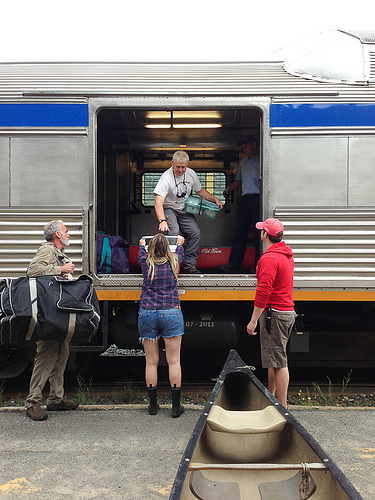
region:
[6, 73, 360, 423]
A scene at a train station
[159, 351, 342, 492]
Front part of a canoie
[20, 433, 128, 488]
Grey patch of train platform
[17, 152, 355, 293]
A train's cargo hold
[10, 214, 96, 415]
Man carrying a large black bag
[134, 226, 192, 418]
Woman wearing jens shorts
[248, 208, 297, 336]
Man wearing red sweatshirt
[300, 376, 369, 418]
Edge of the train platform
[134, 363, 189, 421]
Person wearing black boots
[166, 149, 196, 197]
Man with grey hair and white shirt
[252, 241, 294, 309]
a red coat with a hood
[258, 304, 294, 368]
a pair of olive colored shorts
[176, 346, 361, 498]
a small row boat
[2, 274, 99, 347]
large black dufflebag with white trim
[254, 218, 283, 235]
a red ball cap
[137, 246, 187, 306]
purple long sleeve plaid shirt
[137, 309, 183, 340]
a pair of cut off shorts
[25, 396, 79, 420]
a pair of dingy brown shoes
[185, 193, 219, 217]
blue plastic container with lid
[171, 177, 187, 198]
a pair of sunglasses with neck strap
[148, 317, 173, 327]
LADY WEARING BLUE SHORTS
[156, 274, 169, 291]
LADY HAS ON PLAID SHIRT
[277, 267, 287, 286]
MAN HAS ON A RED SWEATER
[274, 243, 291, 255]
HOOD ON THE BACK OF SWEATER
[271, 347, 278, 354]
MAN HAS ON SHORTS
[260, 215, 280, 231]
MAN WEARING A RED CAP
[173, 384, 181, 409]
LADY HAS ON BROWN BOOTS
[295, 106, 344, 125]
BLUE ON THE TRAIN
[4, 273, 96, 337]
BIG BAG ON MAN SHOULDER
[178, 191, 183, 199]
GLASSES ON A STRING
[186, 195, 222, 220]
man holding a green suitcase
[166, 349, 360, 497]
a small boat on a cement road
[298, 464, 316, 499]
rope attached to a wooden stick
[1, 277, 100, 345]
a big black bag with white lines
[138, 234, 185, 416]
a woman reaching to grab her luggage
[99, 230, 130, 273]
a purple bag inside a train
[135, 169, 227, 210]
a black grilled window in a train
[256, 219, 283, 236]
man wearing a red cap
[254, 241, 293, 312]
man wearing a red sweater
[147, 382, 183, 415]
a woman wearing black boots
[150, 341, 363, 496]
the canoe beside the train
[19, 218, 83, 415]
the man holding the bag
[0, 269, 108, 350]
the bag is large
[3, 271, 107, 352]
the bag is black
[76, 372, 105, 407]
weeds under the train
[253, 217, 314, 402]
the man wearing the red hoodie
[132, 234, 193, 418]
the woman holding cooler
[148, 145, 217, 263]
the man loading the train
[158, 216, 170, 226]
the watch on the wrist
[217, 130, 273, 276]
the conductor on the train